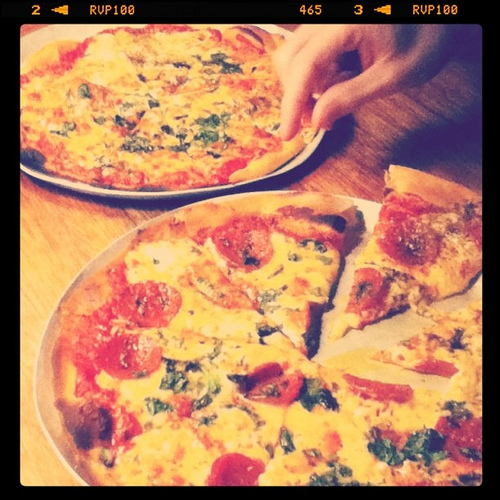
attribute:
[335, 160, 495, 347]
pizza — sliced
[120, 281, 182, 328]
pepperoni — sliced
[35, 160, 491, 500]
pizza — pepperoni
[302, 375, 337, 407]
parsley — small 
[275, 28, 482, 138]
hand — person's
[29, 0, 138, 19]
text — 2 < RUP100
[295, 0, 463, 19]
text — 465 3 < RUP100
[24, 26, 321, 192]
pizza — cheese, medium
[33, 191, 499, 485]
plate — white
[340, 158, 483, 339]
pizza slice — pictured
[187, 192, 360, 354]
pizza slice — pictured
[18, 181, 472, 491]
crust — golden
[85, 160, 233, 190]
sauce — red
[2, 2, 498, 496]
border — black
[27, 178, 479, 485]
pizza plate — aluminum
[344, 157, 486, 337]
pizza — sliced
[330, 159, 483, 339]
pizza — sliced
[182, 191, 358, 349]
pizza — sliced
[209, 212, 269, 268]
pepperoni — red, sliced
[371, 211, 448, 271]
pepperoni — sliced, red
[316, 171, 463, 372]
pizza — sliced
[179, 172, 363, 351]
pizza — sliced